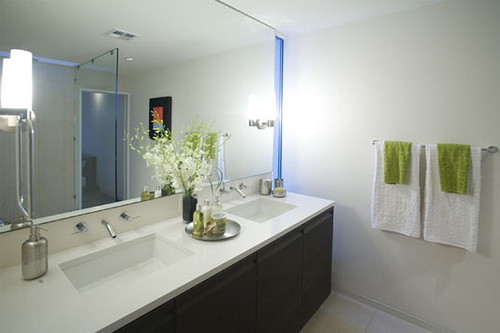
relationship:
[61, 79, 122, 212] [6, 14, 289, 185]
door reflected in mirror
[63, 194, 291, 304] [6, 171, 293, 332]
sinks on countertop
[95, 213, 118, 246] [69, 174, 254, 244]
faucets built into wall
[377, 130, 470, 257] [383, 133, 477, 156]
towels hanging on rack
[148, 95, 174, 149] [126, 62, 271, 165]
artwork hangs on wall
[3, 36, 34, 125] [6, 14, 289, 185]
light hangs on mirror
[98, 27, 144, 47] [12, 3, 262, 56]
vent on ceiling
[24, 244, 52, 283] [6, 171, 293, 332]
soap dispenser on countertop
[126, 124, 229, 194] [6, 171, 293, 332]
flowers on countertop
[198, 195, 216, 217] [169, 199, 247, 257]
lotion on tray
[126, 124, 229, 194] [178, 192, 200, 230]
flowers in vase